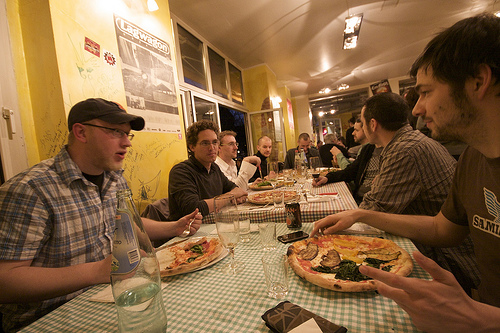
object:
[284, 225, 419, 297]
pizza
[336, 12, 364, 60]
light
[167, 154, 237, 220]
sweater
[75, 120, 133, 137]
glasses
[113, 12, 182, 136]
poster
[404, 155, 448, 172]
ground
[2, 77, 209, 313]
man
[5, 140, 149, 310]
shirt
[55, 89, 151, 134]
cap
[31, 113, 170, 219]
writing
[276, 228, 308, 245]
cellphone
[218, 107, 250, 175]
open door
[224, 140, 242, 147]
glasses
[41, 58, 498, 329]
people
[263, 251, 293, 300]
glass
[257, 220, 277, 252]
glass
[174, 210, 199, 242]
fork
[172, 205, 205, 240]
hand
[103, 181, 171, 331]
bottle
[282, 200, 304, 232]
can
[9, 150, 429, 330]
table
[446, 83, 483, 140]
beard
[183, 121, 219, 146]
hair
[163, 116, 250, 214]
man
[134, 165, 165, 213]
drawing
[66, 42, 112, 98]
drawing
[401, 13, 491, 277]
person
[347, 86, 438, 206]
person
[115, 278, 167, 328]
water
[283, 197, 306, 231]
drink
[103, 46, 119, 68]
picture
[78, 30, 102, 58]
picture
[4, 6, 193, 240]
wall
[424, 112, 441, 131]
moustache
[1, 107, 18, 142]
knob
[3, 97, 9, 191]
window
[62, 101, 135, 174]
head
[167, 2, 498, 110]
ceiling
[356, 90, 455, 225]
person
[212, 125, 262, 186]
person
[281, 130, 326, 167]
person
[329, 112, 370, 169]
person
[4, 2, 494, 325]
restaurant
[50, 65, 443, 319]
establishment